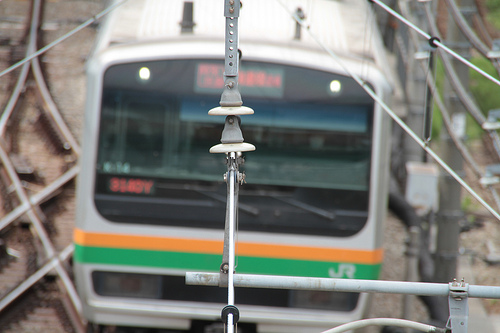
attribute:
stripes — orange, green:
[83, 224, 381, 298]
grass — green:
[414, 56, 494, 153]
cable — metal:
[280, 1, 485, 203]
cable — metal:
[372, 0, 484, 74]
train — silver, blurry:
[70, 1, 394, 331]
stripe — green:
[71, 241, 382, 278]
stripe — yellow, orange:
[71, 228, 384, 262]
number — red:
[108, 176, 119, 189]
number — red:
[119, 177, 128, 192]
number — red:
[123, 177, 134, 192]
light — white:
[135, 64, 152, 81]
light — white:
[328, 77, 342, 95]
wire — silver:
[279, 0, 485, 204]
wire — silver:
[372, 0, 484, 72]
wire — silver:
[362, 5, 373, 86]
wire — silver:
[357, 0, 371, 83]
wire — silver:
[419, 39, 429, 140]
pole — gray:
[183, 270, 484, 300]